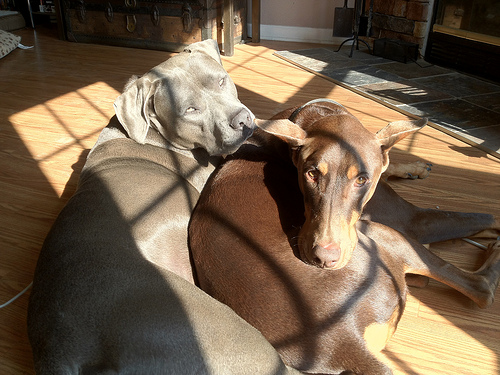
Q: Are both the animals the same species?
A: Yes, all the animals are dogs.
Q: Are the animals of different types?
A: No, all the animals are dogs.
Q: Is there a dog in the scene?
A: Yes, there is a dog.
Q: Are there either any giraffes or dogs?
A: Yes, there is a dog.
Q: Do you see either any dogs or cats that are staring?
A: Yes, the dog is staring.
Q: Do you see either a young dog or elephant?
A: Yes, there is a young dog.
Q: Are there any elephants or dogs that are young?
A: Yes, the dog is young.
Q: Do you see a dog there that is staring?
A: Yes, there is a dog that is staring.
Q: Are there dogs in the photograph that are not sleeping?
A: Yes, there is a dog that is staring.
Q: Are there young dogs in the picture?
A: Yes, there is a young dog.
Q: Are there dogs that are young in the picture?
A: Yes, there is a young dog.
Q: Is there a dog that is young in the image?
A: Yes, there is a young dog.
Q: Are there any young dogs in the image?
A: Yes, there is a young dog.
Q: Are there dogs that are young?
A: Yes, there is a dog that is young.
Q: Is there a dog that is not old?
A: Yes, there is an young dog.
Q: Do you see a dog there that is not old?
A: Yes, there is an young dog.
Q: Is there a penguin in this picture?
A: No, there are no penguins.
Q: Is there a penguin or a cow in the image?
A: No, there are no penguins or cows.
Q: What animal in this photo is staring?
A: The animal is a dog.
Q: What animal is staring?
A: The animal is a dog.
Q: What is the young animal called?
A: The animal is a dog.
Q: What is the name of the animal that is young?
A: The animal is a dog.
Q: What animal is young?
A: The animal is a dog.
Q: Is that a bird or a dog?
A: That is a dog.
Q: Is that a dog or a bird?
A: That is a dog.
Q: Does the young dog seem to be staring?
A: Yes, the dog is staring.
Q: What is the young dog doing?
A: The dog is staring.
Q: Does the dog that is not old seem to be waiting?
A: No, the dog is staring.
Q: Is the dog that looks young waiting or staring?
A: The dog is staring.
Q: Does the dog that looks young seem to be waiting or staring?
A: The dog is staring.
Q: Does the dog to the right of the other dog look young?
A: Yes, the dog is young.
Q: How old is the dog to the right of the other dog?
A: The dog is young.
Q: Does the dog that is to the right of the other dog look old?
A: No, the dog is young.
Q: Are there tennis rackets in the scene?
A: No, there are no tennis rackets.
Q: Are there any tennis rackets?
A: No, there are no tennis rackets.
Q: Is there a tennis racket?
A: No, there are no rackets.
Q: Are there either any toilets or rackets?
A: No, there are no rackets or toilets.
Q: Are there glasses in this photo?
A: No, there are no glasses.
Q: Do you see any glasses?
A: No, there are no glasses.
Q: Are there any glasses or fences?
A: No, there are no glasses or fences.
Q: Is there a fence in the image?
A: No, there are no fences.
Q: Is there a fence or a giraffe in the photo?
A: No, there are no fences or giraffes.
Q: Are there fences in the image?
A: No, there are no fences.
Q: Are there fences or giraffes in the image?
A: No, there are no fences or giraffes.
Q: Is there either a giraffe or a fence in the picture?
A: No, there are no fences or giraffes.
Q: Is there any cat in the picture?
A: No, there are no cats.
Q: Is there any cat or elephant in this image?
A: No, there are no cats or elephants.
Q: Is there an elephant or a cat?
A: No, there are no cats or elephants.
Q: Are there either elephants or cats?
A: No, there are no cats or elephants.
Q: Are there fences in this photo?
A: No, there are no fences.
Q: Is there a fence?
A: No, there are no fences.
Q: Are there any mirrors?
A: No, there are no mirrors.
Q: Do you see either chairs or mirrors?
A: No, there are no mirrors or chairs.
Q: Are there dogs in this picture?
A: Yes, there is a dog.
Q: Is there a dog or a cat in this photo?
A: Yes, there is a dog.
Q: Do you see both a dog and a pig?
A: No, there is a dog but no pigs.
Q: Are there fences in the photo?
A: No, there are no fences.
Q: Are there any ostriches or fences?
A: No, there are no fences or ostriches.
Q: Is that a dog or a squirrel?
A: That is a dog.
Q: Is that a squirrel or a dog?
A: That is a dog.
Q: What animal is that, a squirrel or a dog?
A: That is a dog.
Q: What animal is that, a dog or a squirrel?
A: That is a dog.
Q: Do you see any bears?
A: No, there are no bears.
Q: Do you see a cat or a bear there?
A: No, there are no bears or cats.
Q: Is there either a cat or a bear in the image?
A: No, there are no bears or cats.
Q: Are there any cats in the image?
A: No, there are no cats.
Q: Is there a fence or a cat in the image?
A: No, there are no cats or fences.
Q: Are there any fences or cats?
A: No, there are no cats or fences.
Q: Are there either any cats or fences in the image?
A: No, there are no cats or fences.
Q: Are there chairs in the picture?
A: No, there are no chairs.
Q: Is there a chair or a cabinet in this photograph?
A: No, there are no chairs or cabinets.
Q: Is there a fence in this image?
A: No, there are no fences.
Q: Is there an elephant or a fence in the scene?
A: No, there are no fences or elephants.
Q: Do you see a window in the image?
A: Yes, there is a window.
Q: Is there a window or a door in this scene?
A: Yes, there is a window.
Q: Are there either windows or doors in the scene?
A: Yes, there is a window.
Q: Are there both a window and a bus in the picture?
A: No, there is a window but no buses.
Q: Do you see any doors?
A: No, there are no doors.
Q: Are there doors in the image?
A: No, there are no doors.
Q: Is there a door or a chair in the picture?
A: No, there are no doors or chairs.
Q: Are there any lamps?
A: No, there are no lamps.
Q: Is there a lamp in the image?
A: No, there are no lamps.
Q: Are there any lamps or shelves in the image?
A: No, there are no lamps or shelves.